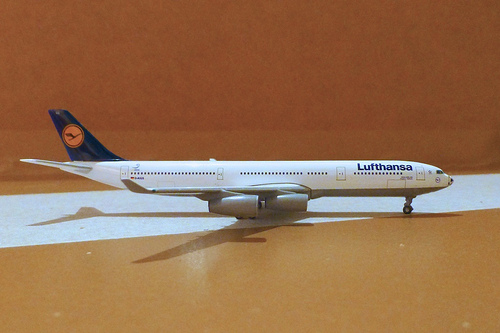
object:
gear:
[402, 204, 416, 214]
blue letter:
[385, 164, 392, 172]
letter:
[357, 162, 412, 171]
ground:
[0, 169, 498, 333]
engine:
[207, 195, 259, 218]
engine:
[265, 192, 308, 213]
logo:
[59, 123, 86, 149]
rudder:
[48, 106, 126, 160]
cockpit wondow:
[435, 169, 445, 174]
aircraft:
[19, 106, 454, 220]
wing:
[121, 179, 295, 203]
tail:
[39, 103, 119, 159]